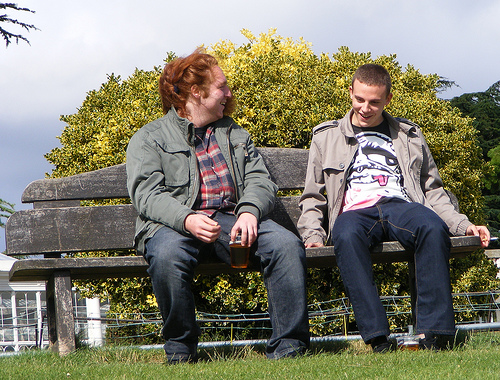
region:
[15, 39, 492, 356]
2 guys on a bench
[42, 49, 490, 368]
2 guys on a bench laughing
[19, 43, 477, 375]
2 guys on a bench sitting together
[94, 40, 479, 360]
2 young men on a bench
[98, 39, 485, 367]
2 young sitting men on a bench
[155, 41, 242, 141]
a guy's head with messed up hair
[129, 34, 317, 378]
a guy holding a glass of liquid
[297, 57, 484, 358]
a young man wearing blue jeans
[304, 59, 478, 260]
a young man wearing a grey jacket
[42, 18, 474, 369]
2 guys on a bench with a big bush behind them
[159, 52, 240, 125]
red hair on a man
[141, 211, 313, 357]
blue jeans on a man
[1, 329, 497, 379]
grass under a bench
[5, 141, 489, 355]
an old wooden bench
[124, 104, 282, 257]
a grey green jacket on a man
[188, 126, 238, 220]
a red and blue plaid shirt on a man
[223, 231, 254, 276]
a brown drink in a man's hand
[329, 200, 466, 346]
dark blue jeans on a man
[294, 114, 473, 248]
a grey jacket on a man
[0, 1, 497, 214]
a grey blue sky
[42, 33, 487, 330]
a large green tree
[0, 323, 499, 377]
a section of green grass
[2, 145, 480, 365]
part of a gray wooden bench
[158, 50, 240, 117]
a man's orange hair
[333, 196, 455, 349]
a man's blue jean pants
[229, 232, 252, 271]
a glass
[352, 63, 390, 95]
a man's short cut hair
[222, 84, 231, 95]
the nose of a man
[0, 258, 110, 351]
part of a white building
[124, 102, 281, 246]
a man's gray jacket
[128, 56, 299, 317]
person sitting on wooden bench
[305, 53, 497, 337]
person sitting on wooden bench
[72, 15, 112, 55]
white clouds in blue sky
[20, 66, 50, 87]
white clouds in blue sky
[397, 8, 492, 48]
white clouds in blue sky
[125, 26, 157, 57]
white clouds in blue sky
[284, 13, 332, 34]
white clouds in blue sky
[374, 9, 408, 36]
white clouds in blue sky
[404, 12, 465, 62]
white clouds in blue sky